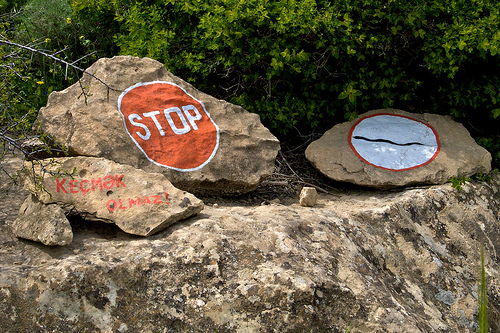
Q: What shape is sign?
A: Round.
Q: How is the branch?
A: Dead.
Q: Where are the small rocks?
A: Larger rock.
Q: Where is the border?
A: On sign.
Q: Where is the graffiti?
A: On stone.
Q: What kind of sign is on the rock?
A: Stop sign.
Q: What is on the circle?
A: A stop sign.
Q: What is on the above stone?
A: Big white circle.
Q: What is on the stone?
A: Graffiti is on the stone.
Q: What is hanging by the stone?
A: A empty branch.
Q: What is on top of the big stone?
A: Couple small stone.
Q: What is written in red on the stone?
A: Graffiti.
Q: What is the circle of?
A: It is a stop sign.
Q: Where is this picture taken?
A: In the woods.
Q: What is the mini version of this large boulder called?
A: Rock.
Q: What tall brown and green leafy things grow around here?
A: Trees.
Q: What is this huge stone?
A: Boulder.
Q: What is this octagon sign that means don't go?
A: Stop sign.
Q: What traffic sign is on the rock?
A: Stop.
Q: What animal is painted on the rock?
A: Snake.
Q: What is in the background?
A: Trees.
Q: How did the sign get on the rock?
A: Paint.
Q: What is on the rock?
A: Painted signs.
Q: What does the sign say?
A: Stop.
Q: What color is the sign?
A: Red and White.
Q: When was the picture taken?
A: Daytime.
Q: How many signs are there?
A: Two.